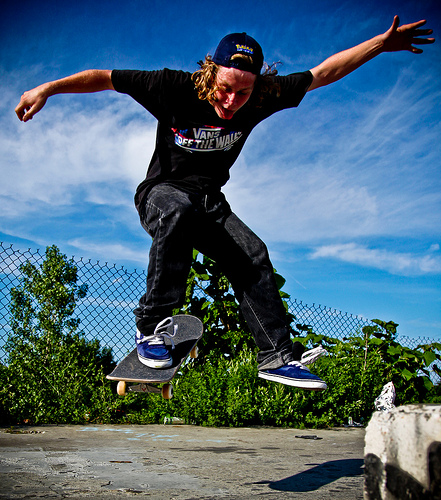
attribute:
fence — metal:
[1, 243, 434, 421]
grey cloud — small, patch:
[284, 185, 308, 205]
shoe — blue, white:
[259, 354, 332, 391]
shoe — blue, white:
[259, 357, 327, 392]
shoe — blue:
[134, 328, 173, 367]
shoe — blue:
[257, 357, 326, 389]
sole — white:
[137, 353, 173, 367]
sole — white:
[257, 371, 325, 389]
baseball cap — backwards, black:
[204, 27, 267, 74]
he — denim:
[9, 6, 439, 400]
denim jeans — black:
[132, 176, 308, 373]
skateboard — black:
[104, 311, 202, 401]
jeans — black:
[131, 181, 311, 364]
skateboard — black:
[106, 310, 203, 385]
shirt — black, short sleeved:
[115, 70, 310, 209]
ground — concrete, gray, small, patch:
[121, 432, 281, 469]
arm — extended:
[264, 12, 438, 122]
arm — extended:
[4, 60, 189, 126]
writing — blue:
[80, 421, 235, 449]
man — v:
[17, 13, 375, 401]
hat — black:
[218, 31, 259, 72]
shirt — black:
[141, 114, 268, 187]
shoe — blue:
[239, 347, 331, 390]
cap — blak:
[221, 19, 269, 64]